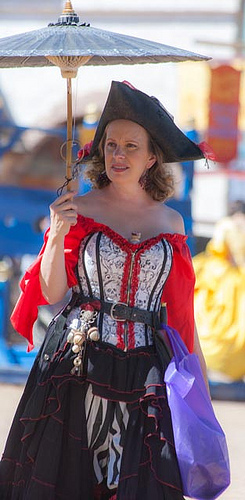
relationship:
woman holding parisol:
[0, 77, 210, 499] [0, 1, 207, 227]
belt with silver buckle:
[70, 292, 167, 328] [110, 299, 128, 321]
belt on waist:
[70, 292, 167, 328] [70, 283, 167, 334]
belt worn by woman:
[69, 291, 162, 328] [3, 118, 192, 498]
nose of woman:
[111, 141, 123, 160] [3, 118, 192, 498]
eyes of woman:
[106, 140, 136, 148] [20, 110, 194, 481]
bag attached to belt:
[160, 322, 237, 499] [69, 291, 162, 328]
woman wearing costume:
[27, 69, 232, 498] [8, 212, 196, 499]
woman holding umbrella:
[27, 69, 232, 498] [1, 0, 233, 85]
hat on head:
[73, 79, 216, 168] [102, 120, 146, 182]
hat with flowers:
[73, 79, 216, 168] [76, 134, 96, 159]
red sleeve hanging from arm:
[167, 234, 194, 354] [188, 316, 208, 390]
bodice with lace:
[71, 230, 174, 350] [5, 374, 186, 493]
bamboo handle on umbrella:
[43, 53, 94, 206] [1, 11, 211, 213]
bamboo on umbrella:
[60, 0, 76, 15] [0, 0, 211, 66]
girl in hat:
[1, 80, 211, 498] [94, 81, 178, 158]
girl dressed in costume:
[1, 80, 211, 498] [0, 212, 196, 498]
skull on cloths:
[104, 281, 116, 301] [93, 235, 166, 346]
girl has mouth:
[1, 80, 211, 498] [106, 159, 142, 176]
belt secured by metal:
[70, 292, 167, 328] [107, 297, 130, 322]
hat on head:
[73, 78, 214, 169] [87, 81, 170, 195]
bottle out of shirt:
[129, 231, 141, 244] [7, 210, 207, 402]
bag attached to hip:
[160, 322, 237, 499] [37, 316, 166, 373]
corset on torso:
[12, 209, 196, 352] [52, 237, 175, 354]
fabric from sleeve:
[8, 273, 43, 353] [63, 227, 79, 281]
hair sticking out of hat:
[146, 141, 180, 200] [84, 72, 219, 175]